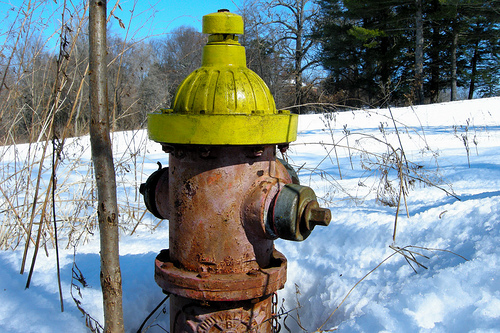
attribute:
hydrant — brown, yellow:
[142, 83, 392, 288]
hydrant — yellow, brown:
[174, 134, 261, 271]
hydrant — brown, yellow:
[152, 129, 257, 271]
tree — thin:
[68, 101, 147, 298]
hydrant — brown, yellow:
[127, 222, 347, 291]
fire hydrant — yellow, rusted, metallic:
[138, 10, 329, 331]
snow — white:
[0, 96, 499, 331]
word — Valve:
[216, 311, 252, 323]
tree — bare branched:
[244, 3, 324, 113]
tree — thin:
[88, 1, 123, 331]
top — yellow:
[145, 8, 299, 145]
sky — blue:
[0, 1, 327, 75]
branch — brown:
[391, 150, 408, 247]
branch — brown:
[389, 240, 430, 273]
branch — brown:
[364, 156, 459, 202]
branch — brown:
[340, 121, 360, 169]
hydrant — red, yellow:
[139, 8, 330, 326]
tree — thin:
[84, 1, 128, 327]